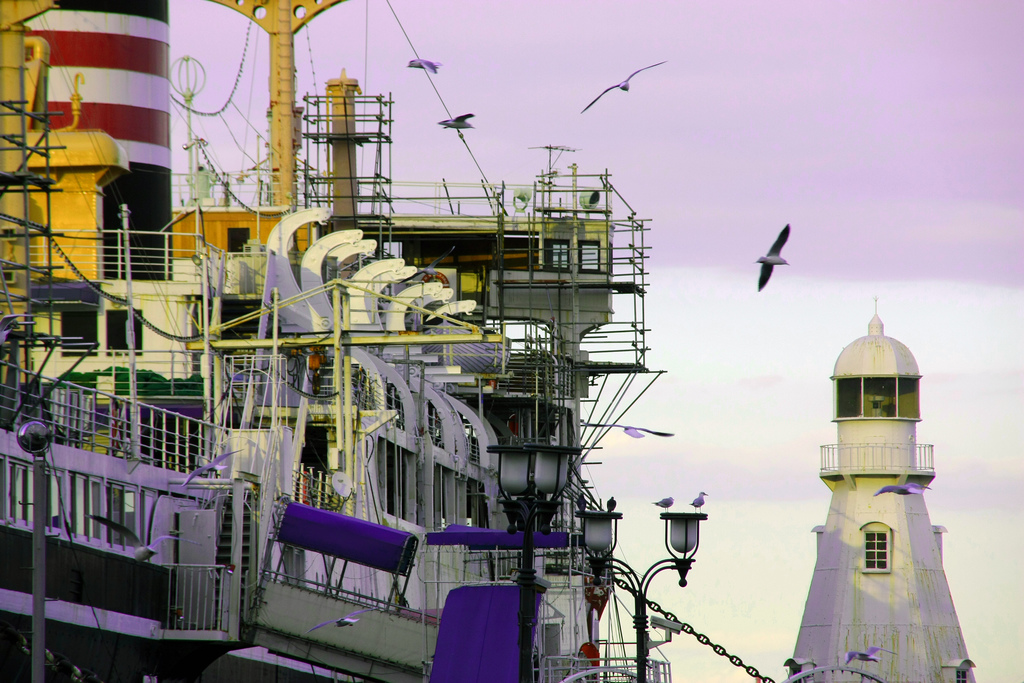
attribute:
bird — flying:
[586, 63, 653, 126]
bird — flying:
[744, 221, 797, 280]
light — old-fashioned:
[643, 509, 736, 672]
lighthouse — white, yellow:
[721, 267, 977, 680]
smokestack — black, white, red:
[40, 2, 252, 232]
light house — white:
[794, 320, 963, 666]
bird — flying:
[754, 221, 794, 295]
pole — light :
[567, 488, 721, 677]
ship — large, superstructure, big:
[16, 16, 656, 658]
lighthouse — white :
[777, 312, 972, 680]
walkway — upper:
[811, 434, 945, 499]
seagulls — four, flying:
[403, 45, 823, 294]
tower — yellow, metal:
[223, 4, 358, 219]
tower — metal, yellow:
[228, 2, 343, 203]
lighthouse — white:
[787, 321, 989, 680]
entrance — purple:
[264, 494, 546, 674]